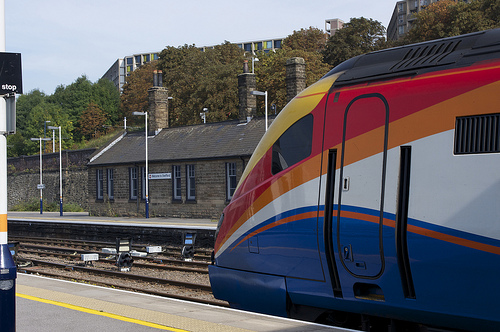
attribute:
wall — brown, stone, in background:
[29, 157, 104, 217]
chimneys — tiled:
[145, 59, 307, 131]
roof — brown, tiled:
[100, 124, 271, 175]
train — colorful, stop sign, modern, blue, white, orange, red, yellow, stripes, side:
[230, 54, 490, 328]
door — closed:
[337, 88, 394, 280]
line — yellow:
[27, 292, 132, 324]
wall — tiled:
[90, 169, 236, 207]